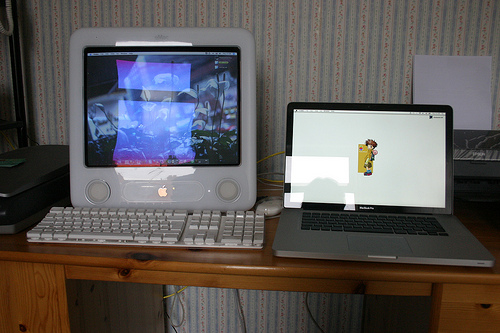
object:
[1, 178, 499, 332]
desk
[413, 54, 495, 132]
paper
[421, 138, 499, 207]
printer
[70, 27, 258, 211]
monitor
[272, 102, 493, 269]
laptop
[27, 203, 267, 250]
keyboard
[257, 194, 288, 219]
mouse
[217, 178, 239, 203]
dial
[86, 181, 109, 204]
dial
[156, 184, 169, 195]
logo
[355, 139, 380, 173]
image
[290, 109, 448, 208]
screen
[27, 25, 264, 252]
computer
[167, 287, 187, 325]
cords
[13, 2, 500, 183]
wallpaper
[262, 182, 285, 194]
cord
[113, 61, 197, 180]
sunlight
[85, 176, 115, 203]
knobs